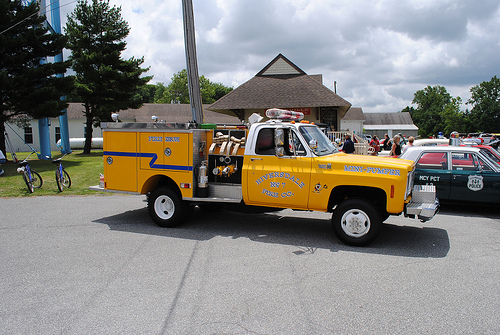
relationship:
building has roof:
[363, 110, 419, 143] [362, 111, 413, 124]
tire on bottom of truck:
[329, 197, 382, 245] [99, 106, 440, 246]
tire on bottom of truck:
[145, 184, 188, 228] [99, 106, 440, 246]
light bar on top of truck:
[265, 106, 306, 122] [99, 106, 440, 246]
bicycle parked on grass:
[50, 154, 71, 194] [1, 148, 115, 197]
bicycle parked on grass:
[13, 148, 43, 195] [1, 148, 115, 197]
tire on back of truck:
[145, 184, 188, 228] [99, 106, 440, 246]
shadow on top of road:
[91, 198, 449, 259] [1, 189, 499, 334]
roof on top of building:
[204, 52, 350, 120] [204, 51, 350, 132]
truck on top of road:
[99, 106, 440, 246] [1, 189, 499, 334]